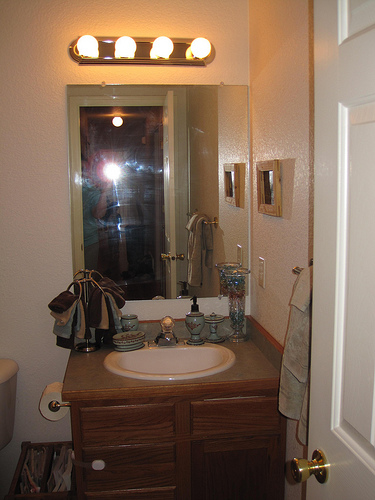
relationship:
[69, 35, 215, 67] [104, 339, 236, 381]
light over sink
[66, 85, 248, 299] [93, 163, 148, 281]
mirror has a reflection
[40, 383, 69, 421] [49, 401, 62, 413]
toilet paper on a roll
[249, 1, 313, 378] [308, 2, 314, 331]
wall has a woodframe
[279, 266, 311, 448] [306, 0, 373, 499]
towel near door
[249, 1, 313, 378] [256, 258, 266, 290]
wall has an outlet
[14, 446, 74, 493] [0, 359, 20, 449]
magazines are beside toliet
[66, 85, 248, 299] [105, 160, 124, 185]
mirror has a flash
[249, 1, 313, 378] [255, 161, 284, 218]
wall has a picture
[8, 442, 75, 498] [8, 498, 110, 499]
magazine rack on floor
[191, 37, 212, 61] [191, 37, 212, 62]
light in shape of circle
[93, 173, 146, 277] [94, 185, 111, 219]
person has an arm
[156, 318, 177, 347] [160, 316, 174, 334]
faucet has a handle